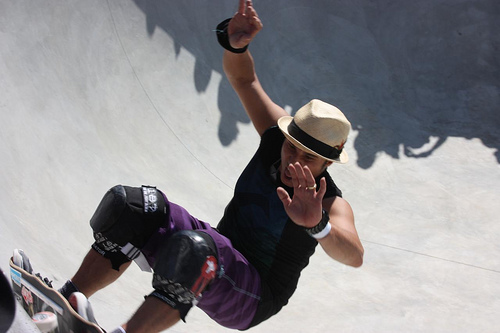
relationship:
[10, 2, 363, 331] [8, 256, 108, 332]
man on skateboard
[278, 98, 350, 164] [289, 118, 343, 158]
hat with stripe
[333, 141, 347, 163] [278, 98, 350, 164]
feather in hat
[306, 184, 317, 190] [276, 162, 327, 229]
ring on hand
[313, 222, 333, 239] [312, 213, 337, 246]
bracelet on wrist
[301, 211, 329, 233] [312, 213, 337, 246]
bracelet on wrist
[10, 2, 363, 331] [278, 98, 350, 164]
man wearing hat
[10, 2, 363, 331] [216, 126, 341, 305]
man wearing top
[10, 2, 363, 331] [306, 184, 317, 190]
man has ring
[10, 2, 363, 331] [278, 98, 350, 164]
man has hat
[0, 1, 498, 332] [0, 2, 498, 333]
wall of park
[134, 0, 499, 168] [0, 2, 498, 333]
shadow in park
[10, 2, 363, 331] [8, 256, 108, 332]
man riding skateboard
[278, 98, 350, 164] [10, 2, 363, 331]
hat on man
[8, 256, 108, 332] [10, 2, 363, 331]
skateboard ridden by man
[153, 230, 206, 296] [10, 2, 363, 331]
pad worn by man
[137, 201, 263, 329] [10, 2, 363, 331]
shorts worn by man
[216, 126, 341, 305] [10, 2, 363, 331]
top worn by man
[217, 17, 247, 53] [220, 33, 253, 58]
watch on wrist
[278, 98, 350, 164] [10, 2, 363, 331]
hat worn by man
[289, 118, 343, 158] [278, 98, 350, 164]
stripe around hat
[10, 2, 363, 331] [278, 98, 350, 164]
man in hat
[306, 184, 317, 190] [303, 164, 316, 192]
ring on finger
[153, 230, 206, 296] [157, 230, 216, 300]
pad on knee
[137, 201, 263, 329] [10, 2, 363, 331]
shorts on man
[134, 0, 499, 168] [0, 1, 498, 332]
shadow on wall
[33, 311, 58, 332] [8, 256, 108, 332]
wheel on skateboard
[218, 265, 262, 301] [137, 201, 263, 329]
stripe on shorts